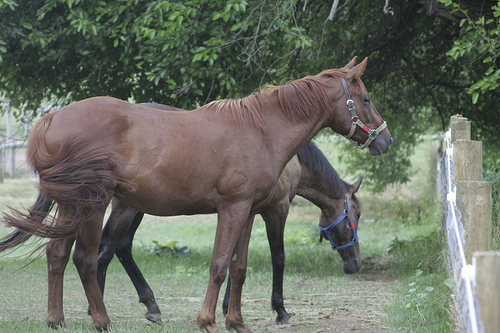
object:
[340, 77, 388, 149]
bridle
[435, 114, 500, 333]
stone wall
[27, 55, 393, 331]
horse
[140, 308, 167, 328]
hoof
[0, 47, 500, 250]
plane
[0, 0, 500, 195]
trees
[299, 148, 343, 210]
neck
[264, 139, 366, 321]
horse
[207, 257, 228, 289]
knee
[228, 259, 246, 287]
knee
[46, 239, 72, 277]
knee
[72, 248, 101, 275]
knee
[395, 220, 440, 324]
grass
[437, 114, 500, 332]
fence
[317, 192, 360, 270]
harness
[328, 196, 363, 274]
face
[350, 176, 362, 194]
ear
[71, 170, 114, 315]
back legs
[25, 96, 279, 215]
body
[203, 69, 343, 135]
hair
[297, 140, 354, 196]
hair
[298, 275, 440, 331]
dirt patch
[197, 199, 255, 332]
leg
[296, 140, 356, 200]
mane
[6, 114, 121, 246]
tail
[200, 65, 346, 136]
mane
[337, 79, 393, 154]
face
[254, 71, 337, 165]
neck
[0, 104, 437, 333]
ground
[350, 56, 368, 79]
ear